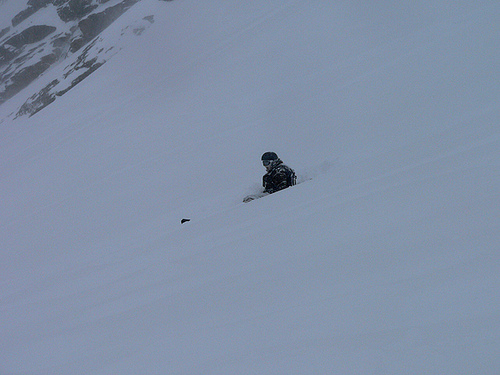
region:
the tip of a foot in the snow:
[180, 214, 189, 226]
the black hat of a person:
[258, 148, 277, 160]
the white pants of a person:
[242, 192, 274, 204]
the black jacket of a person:
[259, 161, 299, 188]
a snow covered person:
[245, 143, 300, 198]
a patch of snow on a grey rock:
[50, 68, 90, 90]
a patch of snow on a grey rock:
[2, 42, 17, 52]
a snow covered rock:
[22, 58, 107, 115]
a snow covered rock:
[4, 33, 70, 100]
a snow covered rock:
[75, 0, 134, 50]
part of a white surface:
[454, 247, 464, 259]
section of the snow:
[272, 324, 285, 337]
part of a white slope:
[214, 277, 226, 283]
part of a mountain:
[378, 279, 400, 288]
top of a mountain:
[278, 252, 314, 277]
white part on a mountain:
[198, 287, 220, 329]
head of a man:
[263, 150, 270, 165]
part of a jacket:
[268, 161, 280, 177]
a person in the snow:
[225, 114, 326, 235]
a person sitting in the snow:
[219, 131, 349, 275]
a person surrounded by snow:
[173, 109, 326, 225]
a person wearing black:
[232, 118, 327, 214]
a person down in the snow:
[200, 106, 311, 209]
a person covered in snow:
[202, 138, 360, 264]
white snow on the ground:
[267, 231, 497, 346]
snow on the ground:
[202, 229, 492, 371]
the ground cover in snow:
[236, 227, 491, 360]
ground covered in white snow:
[250, 248, 465, 373]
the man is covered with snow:
[107, 23, 327, 291]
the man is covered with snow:
[192, 71, 341, 298]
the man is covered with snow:
[252, 174, 361, 369]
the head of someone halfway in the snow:
[257, 148, 278, 166]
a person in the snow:
[257, 149, 299, 195]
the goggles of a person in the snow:
[260, 158, 274, 165]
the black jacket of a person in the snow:
[259, 167, 296, 189]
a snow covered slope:
[2, 2, 499, 372]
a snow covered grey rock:
[19, 36, 109, 124]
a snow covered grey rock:
[0, 23, 51, 62]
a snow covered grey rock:
[7, 46, 66, 95]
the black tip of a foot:
[178, 216, 192, 225]